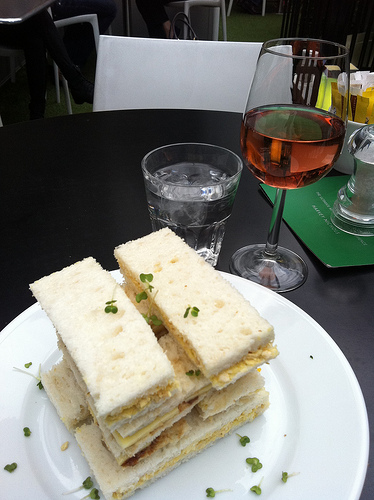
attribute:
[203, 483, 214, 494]
leaf — small, green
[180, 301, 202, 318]
garnish — on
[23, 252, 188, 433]
sandwich — has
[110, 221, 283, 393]
sandwich — has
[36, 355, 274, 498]
sandwich — has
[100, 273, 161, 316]
leaf — small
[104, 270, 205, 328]
leaves — small, green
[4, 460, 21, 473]
plant — green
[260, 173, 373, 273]
green menu — on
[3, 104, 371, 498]
table — has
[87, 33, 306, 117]
chair — by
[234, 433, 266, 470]
leaves — small, green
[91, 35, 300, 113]
chair — white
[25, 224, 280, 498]
sandwiches — on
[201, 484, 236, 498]
plant — green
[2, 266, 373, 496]
plate — white, on, green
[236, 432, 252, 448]
plant — green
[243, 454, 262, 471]
plant — green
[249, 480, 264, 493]
plant — green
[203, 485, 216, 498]
plant — green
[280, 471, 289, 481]
plant — green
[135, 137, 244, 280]
glass — with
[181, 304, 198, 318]
leaves — small, green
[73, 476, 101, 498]
plant — green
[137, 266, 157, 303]
leaves — small, green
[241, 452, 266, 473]
plant — green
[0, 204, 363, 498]
table — has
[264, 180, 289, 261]
stem — glass